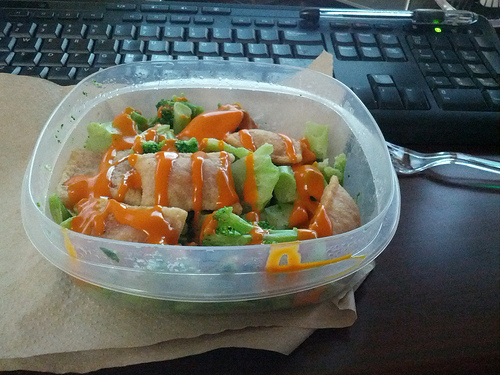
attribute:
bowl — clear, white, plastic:
[20, 37, 404, 315]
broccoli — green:
[61, 97, 346, 250]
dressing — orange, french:
[68, 107, 341, 237]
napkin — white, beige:
[1, 41, 374, 369]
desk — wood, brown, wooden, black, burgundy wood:
[13, 141, 499, 373]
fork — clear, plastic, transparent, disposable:
[375, 132, 500, 177]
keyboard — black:
[2, 1, 499, 146]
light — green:
[433, 26, 443, 34]